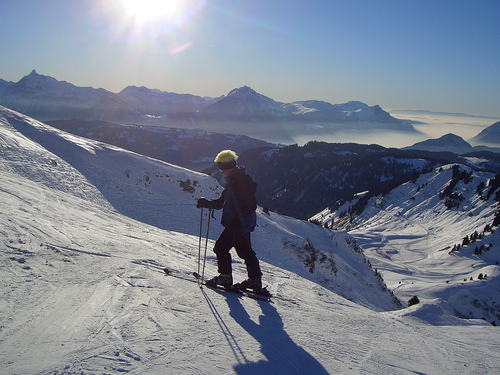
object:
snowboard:
[165, 267, 271, 299]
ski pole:
[201, 201, 213, 288]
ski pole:
[195, 206, 204, 283]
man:
[197, 150, 262, 291]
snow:
[0, 303, 145, 370]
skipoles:
[175, 197, 215, 287]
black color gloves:
[197, 197, 214, 209]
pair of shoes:
[206, 273, 261, 290]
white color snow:
[66, 163, 162, 258]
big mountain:
[14, 69, 116, 121]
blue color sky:
[297, 15, 415, 82]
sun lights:
[85, 1, 200, 44]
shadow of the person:
[208, 289, 324, 373]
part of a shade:
[211, 294, 286, 330]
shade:
[118, 167, 206, 226]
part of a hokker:
[183, 247, 221, 289]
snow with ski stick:
[200, 201, 219, 287]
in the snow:
[190, 279, 281, 313]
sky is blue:
[381, 23, 470, 84]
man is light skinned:
[223, 169, 231, 175]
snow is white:
[294, 299, 378, 364]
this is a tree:
[295, 172, 313, 187]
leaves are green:
[257, 166, 285, 190]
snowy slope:
[6, 133, 166, 317]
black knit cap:
[218, 160, 237, 169]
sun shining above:
[82, 3, 219, 54]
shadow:
[192, 287, 327, 375]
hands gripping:
[196, 197, 212, 209]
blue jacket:
[209, 167, 258, 233]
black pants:
[213, 216, 264, 277]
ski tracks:
[89, 256, 185, 371]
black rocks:
[271, 218, 391, 310]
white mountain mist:
[295, 114, 483, 151]